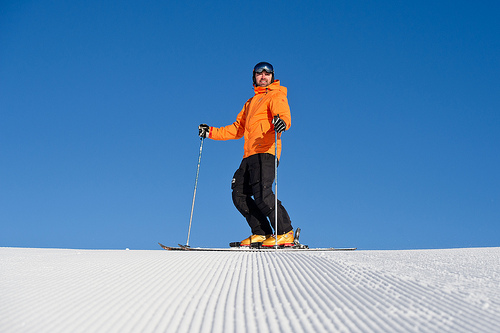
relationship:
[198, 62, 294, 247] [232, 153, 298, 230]
he wearing pants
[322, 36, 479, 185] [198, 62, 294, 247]
sky behind he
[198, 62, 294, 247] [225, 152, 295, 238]
he wearing pants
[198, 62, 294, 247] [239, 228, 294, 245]
he wearing shoes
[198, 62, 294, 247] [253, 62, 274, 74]
he wearing goggles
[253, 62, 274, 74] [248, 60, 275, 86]
goggles are in head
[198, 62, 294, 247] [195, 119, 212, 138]
he are wearing gloves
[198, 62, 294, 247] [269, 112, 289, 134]
he are wearing gloves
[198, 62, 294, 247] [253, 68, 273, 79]
he wearing mustache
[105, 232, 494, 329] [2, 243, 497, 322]
lines in snow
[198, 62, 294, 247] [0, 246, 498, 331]
he standing on snow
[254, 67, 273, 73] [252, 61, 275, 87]
goggles on head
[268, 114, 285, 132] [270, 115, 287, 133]
glove on hand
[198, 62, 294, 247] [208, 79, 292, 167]
he wearing jacket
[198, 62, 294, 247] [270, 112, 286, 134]
he wearing glove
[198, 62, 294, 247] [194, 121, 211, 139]
he wearing glove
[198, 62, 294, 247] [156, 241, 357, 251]
he standing on skis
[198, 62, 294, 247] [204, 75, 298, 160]
he wearing jacket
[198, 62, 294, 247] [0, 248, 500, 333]
he perpendicular to ground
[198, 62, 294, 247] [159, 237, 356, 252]
he on skis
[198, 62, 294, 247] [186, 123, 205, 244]
he holding ski pole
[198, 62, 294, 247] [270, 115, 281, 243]
he holding ski pole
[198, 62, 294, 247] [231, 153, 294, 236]
he wearing pants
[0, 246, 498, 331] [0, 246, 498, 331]
snow on ground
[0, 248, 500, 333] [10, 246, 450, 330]
ground in snow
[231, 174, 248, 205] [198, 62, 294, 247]
knee on he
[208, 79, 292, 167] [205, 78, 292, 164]
jacket wearing jacket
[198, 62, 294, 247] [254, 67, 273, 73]
he with goggles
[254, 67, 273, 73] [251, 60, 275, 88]
goggles on h head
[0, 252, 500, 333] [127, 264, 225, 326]
lines in snow